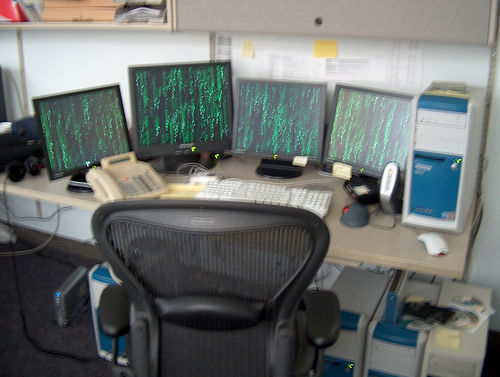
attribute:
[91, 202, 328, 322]
chair — black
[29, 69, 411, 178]
monitor — four, computer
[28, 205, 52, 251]
wires — hanging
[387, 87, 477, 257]
cpu — blue, white